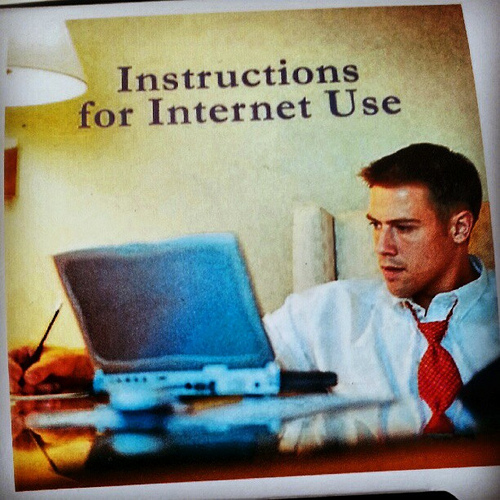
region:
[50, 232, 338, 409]
Grey laptop computer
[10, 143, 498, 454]
Man in business attire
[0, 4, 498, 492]
Poster about internet use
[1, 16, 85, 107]
A white lamp shade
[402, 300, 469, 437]
A red neck tie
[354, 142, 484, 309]
A man's face in profile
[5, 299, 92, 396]
A hand holding a ped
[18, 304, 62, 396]
A black ink pen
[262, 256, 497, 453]
A white dress shirt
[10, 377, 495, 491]
A brown table top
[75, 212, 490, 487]
a laptop on a table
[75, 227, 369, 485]
an open laptop on a table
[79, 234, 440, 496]
a laptop that is open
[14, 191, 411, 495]
a table with a laptop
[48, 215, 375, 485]
a table with an open laptop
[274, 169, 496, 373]
a man working on a laptop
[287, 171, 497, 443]
a man sitting down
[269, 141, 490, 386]
a man wearin ga shirt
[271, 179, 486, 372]
a man wearing a tie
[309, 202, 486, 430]
a man wearing a red tie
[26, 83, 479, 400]
advertisement for internet use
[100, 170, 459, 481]
advertisement for internet use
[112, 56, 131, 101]
Black lettering on a book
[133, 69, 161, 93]
Black lettering on a book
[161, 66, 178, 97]
Black lettering on a book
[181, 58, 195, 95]
Black lettering on a book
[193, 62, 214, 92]
Black lettering on a book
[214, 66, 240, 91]
Black lettering on a book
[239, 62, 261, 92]
Black lettering on a book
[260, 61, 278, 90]
Black lettering on a book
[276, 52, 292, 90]
Black lettering on a book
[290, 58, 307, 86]
Black lettering on a book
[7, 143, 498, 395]
the man sitting in front of the laptop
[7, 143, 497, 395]
the man sitting down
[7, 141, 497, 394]
the man wearing a shirt and tie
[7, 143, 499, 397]
the man holding a pencil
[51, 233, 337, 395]
the laptop in front of the man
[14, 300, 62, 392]
the pencil in the man's hand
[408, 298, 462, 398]
the tie around the man's neck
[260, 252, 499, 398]
the shirt on the man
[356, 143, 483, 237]
the hair on the man's head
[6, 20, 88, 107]
the white lamp shade